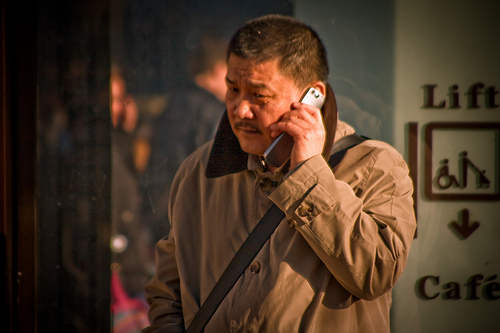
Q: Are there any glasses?
A: No, there are no glasses.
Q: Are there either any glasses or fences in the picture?
A: No, there are no glasses or fences.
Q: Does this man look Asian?
A: Yes, the man is asian.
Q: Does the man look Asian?
A: Yes, the man is asian.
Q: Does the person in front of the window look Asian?
A: Yes, the man is asian.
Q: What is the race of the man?
A: The man is asian.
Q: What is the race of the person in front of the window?
A: The man is asian.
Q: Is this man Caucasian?
A: No, the man is asian.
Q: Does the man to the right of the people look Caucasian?
A: No, the man is asian.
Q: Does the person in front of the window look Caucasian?
A: No, the man is asian.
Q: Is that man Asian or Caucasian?
A: The man is asian.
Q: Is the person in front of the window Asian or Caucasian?
A: The man is asian.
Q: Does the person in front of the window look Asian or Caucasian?
A: The man is asian.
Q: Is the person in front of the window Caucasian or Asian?
A: The man is asian.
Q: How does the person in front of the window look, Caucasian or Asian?
A: The man is asian.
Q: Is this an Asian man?
A: Yes, this is an Asian man.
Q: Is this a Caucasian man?
A: No, this is an Asian man.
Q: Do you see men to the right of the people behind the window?
A: Yes, there is a man to the right of the people.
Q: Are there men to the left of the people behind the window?
A: No, the man is to the right of the people.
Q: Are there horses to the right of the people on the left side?
A: No, there is a man to the right of the people.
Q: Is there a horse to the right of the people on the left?
A: No, there is a man to the right of the people.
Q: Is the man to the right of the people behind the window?
A: Yes, the man is to the right of the people.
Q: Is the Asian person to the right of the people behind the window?
A: Yes, the man is to the right of the people.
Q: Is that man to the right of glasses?
A: No, the man is to the right of the people.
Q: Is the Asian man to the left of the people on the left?
A: No, the man is to the right of the people.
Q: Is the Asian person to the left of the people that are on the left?
A: No, the man is to the right of the people.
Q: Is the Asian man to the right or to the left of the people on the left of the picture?
A: The man is to the right of the people.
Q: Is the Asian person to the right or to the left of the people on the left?
A: The man is to the right of the people.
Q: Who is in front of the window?
A: The man is in front of the window.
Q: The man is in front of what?
A: The man is in front of the window.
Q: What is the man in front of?
A: The man is in front of the window.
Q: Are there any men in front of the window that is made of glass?
A: Yes, there is a man in front of the window.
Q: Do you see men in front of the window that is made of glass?
A: Yes, there is a man in front of the window.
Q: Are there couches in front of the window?
A: No, there is a man in front of the window.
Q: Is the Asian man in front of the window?
A: Yes, the man is in front of the window.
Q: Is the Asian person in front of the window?
A: Yes, the man is in front of the window.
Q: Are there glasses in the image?
A: No, there are no glasses.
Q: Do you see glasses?
A: No, there are no glasses.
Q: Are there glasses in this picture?
A: No, there are no glasses.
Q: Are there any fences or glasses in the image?
A: No, there are no glasses or fences.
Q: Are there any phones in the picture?
A: Yes, there is a phone.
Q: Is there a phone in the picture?
A: Yes, there is a phone.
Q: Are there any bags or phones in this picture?
A: Yes, there is a phone.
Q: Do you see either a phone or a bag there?
A: Yes, there is a phone.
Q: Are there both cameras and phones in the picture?
A: No, there is a phone but no cameras.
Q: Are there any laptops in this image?
A: No, there are no laptops.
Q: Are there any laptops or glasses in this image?
A: No, there are no laptops or glasses.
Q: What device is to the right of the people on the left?
A: The device is a phone.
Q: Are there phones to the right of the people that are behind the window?
A: Yes, there is a phone to the right of the people.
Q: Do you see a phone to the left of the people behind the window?
A: No, the phone is to the right of the people.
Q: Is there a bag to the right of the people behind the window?
A: No, there is a phone to the right of the people.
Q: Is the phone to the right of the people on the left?
A: Yes, the phone is to the right of the people.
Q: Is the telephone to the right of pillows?
A: No, the telephone is to the right of the people.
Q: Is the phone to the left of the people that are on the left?
A: No, the phone is to the right of the people.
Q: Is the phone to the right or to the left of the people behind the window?
A: The phone is to the right of the people.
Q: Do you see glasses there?
A: No, there are no glasses.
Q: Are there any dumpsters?
A: No, there are no dumpsters.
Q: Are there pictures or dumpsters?
A: No, there are no dumpsters or pictures.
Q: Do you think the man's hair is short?
A: Yes, the hair is short.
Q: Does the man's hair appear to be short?
A: Yes, the hair is short.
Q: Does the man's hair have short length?
A: Yes, the hair is short.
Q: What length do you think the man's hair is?
A: The hair is short.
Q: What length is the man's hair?
A: The hair is short.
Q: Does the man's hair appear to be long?
A: No, the hair is short.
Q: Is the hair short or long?
A: The hair is short.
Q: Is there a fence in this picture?
A: No, there are no fences.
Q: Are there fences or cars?
A: No, there are no fences or cars.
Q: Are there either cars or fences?
A: No, there are no fences or cars.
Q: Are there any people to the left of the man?
A: Yes, there are people to the left of the man.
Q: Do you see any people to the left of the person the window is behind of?
A: Yes, there are people to the left of the man.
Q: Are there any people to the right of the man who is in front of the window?
A: No, the people are to the left of the man.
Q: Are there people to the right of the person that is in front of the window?
A: No, the people are to the left of the man.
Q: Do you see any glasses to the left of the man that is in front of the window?
A: No, there are people to the left of the man.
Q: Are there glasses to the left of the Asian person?
A: No, there are people to the left of the man.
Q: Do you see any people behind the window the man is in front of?
A: Yes, there are people behind the window.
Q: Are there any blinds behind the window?
A: No, there are people behind the window.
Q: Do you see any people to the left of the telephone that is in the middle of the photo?
A: Yes, there are people to the left of the phone.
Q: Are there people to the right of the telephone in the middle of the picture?
A: No, the people are to the left of the phone.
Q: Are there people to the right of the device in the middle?
A: No, the people are to the left of the phone.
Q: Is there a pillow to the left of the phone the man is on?
A: No, there are people to the left of the phone.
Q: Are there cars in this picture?
A: No, there are no cars.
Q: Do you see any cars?
A: No, there are no cars.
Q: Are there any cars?
A: No, there are no cars.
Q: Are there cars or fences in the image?
A: No, there are no cars or fences.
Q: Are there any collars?
A: Yes, there is a collar.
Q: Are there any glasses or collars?
A: Yes, there is a collar.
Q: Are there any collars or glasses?
A: Yes, there is a collar.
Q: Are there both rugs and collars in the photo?
A: No, there is a collar but no rugs.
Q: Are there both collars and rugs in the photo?
A: No, there is a collar but no rugs.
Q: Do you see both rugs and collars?
A: No, there is a collar but no rugs.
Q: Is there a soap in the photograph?
A: No, there are no soaps.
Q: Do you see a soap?
A: No, there are no soaps.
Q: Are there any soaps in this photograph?
A: No, there are no soaps.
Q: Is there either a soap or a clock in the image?
A: No, there are no soaps or clocks.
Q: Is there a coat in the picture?
A: Yes, there is a coat.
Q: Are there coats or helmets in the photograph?
A: Yes, there is a coat.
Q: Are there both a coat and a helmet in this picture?
A: No, there is a coat but no helmets.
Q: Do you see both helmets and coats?
A: No, there is a coat but no helmets.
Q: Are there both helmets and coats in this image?
A: No, there is a coat but no helmets.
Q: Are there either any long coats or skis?
A: Yes, there is a long coat.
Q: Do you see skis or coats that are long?
A: Yes, the coat is long.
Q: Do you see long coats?
A: Yes, there is a long coat.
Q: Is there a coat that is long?
A: Yes, there is a coat that is long.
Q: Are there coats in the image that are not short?
A: Yes, there is a long coat.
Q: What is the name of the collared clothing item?
A: The clothing item is a coat.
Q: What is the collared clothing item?
A: The clothing item is a coat.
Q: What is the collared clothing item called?
A: The clothing item is a coat.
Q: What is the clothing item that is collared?
A: The clothing item is a coat.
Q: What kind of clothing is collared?
A: The clothing is a coat.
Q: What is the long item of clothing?
A: The clothing item is a coat.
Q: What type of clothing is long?
A: The clothing is a coat.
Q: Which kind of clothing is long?
A: The clothing is a coat.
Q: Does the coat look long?
A: Yes, the coat is long.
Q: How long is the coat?
A: The coat is long.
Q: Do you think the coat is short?
A: No, the coat is long.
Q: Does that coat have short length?
A: No, the coat is long.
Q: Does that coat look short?
A: No, the coat is long.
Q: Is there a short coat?
A: No, there is a coat but it is long.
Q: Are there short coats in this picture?
A: No, there is a coat but it is long.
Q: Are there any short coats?
A: No, there is a coat but it is long.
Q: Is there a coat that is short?
A: No, there is a coat but it is long.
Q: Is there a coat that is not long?
A: No, there is a coat but it is long.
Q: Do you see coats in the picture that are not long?
A: No, there is a coat but it is long.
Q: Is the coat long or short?
A: The coat is long.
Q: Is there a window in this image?
A: Yes, there is a window.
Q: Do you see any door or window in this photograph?
A: Yes, there is a window.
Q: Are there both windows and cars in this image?
A: No, there is a window but no cars.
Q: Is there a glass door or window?
A: Yes, there is a glass window.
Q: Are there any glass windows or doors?
A: Yes, there is a glass window.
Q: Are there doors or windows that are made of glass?
A: Yes, the window is made of glass.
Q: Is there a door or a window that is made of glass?
A: Yes, the window is made of glass.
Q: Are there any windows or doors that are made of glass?
A: Yes, the window is made of glass.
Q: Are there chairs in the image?
A: No, there are no chairs.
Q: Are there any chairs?
A: No, there are no chairs.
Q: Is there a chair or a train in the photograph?
A: No, there are no chairs or trains.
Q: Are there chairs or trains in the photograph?
A: No, there are no chairs or trains.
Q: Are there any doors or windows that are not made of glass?
A: No, there is a window but it is made of glass.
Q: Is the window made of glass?
A: Yes, the window is made of glass.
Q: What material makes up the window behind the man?
A: The window is made of glass.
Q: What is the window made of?
A: The window is made of glass.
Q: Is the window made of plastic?
A: No, the window is made of glass.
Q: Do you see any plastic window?
A: No, there is a window but it is made of glass.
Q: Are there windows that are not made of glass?
A: No, there is a window but it is made of glass.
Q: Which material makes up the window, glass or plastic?
A: The window is made of glass.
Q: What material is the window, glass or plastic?
A: The window is made of glass.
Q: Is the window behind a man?
A: Yes, the window is behind a man.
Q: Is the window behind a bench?
A: No, the window is behind a man.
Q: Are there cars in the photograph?
A: No, there are no cars.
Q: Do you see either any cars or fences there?
A: No, there are no cars or fences.